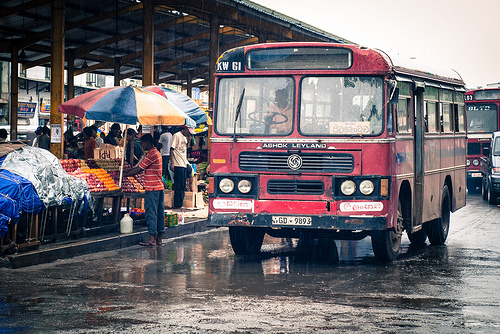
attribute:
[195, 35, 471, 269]
bus — black, red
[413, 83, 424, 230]
door — loading, unloading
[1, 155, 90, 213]
tarps — blue and grey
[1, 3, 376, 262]
outdoor market — open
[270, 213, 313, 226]
license plate — white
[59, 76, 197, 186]
umbrella — red, blue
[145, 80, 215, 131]
umbrella — yellow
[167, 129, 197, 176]
man — selling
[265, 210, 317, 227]
lettering — black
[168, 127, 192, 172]
shirt — white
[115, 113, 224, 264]
man — striped, white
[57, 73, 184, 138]
umbrellas — colorful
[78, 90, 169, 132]
umbrella — colored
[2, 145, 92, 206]
tarp — gray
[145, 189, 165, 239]
pants — blue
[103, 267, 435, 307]
water — floating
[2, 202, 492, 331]
water — floating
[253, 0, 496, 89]
skies — grey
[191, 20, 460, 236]
bus — red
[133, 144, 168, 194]
shirt — striped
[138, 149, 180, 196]
shirt — orange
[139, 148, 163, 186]
shirt — orange